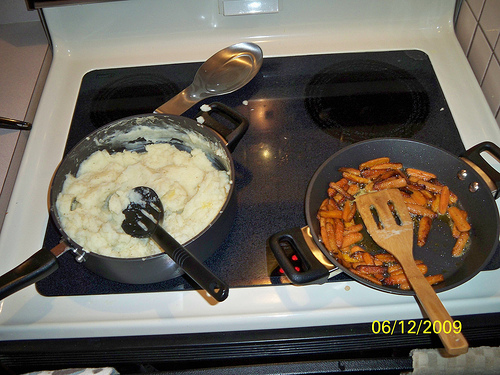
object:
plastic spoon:
[109, 185, 229, 301]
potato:
[57, 118, 230, 258]